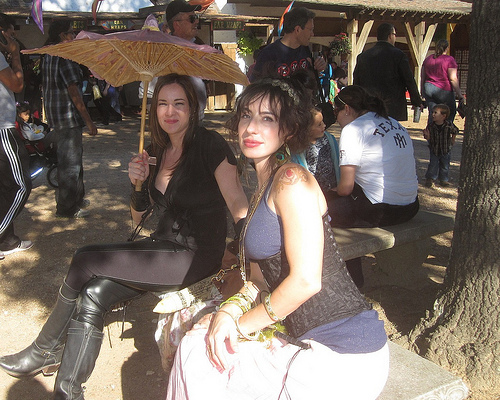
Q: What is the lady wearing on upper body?
A: A corset.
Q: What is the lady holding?
A: A umbrella.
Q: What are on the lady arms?
A: Bangles.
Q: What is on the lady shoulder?
A: A tattoo.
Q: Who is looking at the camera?
A: The ladies.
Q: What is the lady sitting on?
A: A bench.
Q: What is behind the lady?
A: A tree.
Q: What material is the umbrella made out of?
A: Wood.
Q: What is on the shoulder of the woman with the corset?
A: Tattoo.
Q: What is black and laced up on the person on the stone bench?
A: Corset.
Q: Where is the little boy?
A: Standing in front of the lady with the pink shirt.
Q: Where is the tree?
A: Behind the stone bench?.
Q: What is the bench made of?
A: Stone.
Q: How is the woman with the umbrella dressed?
A: All in black.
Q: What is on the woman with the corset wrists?
A: Bracelets.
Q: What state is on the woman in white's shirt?
A: Texas.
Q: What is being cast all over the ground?
A: Shadows.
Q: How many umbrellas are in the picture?
A: One.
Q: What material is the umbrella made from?
A: Straw.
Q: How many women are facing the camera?
A: Two.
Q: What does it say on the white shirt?
A: Texas.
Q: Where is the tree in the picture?
A: To the far right.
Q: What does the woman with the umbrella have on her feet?
A: Boots.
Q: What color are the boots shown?
A: Black.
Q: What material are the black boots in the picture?
A: Leather.